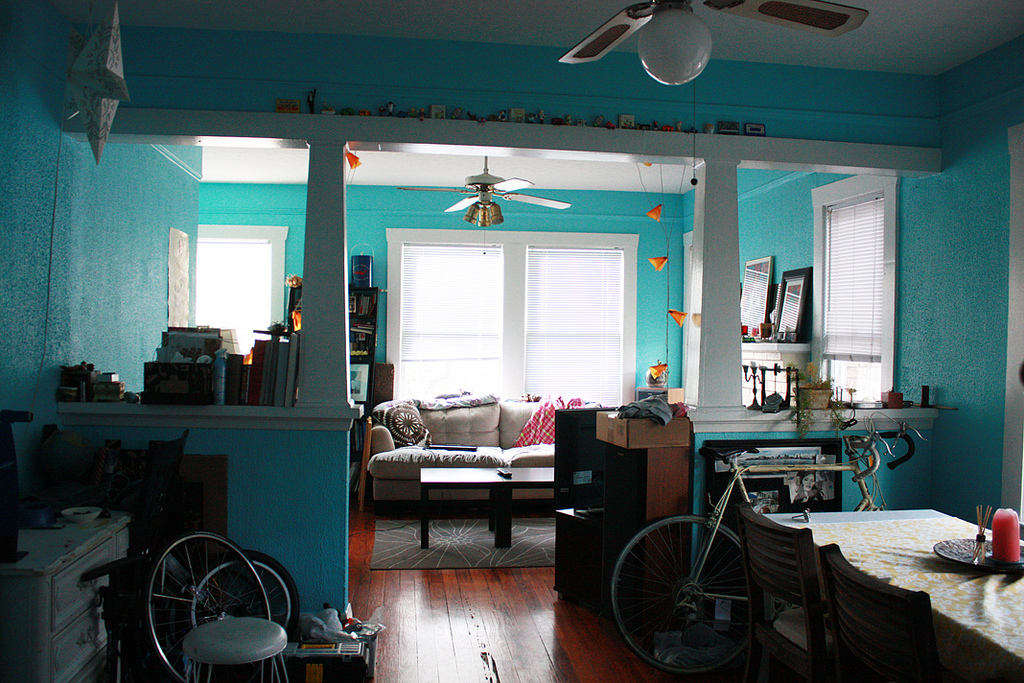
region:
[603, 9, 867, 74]
Ceiling fan hanging down from ceiling.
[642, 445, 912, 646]
Bike leaning against wall.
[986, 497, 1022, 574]
Red candle on plate on table.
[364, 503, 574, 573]
Gray and white area rug in room.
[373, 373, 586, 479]
Light colored in couch in room.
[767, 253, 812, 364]
Black framed picture leaning against wall.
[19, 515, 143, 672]
White distressed dresser in room.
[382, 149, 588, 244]
a ceiling fan with lights in the middle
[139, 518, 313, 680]
a set of spare bicycle tires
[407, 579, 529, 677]
dark stained wooden floors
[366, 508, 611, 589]
a piece of rug or carpet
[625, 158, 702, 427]
a decorative light stand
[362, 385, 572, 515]
a white couch with pillows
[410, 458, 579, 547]
a small wooden table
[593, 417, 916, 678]
a bicycle leaning on a wall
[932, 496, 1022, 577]
a candle and incense on a tray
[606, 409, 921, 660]
bicycle next to the wall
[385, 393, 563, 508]
couch under the windows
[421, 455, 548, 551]
coffee table in the living room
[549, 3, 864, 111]
ceiling fan with globe light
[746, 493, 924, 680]
chairs at the table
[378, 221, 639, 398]
windows behind the couch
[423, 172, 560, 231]
ceiling fan in the living room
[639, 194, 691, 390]
orange light fixtures next to the couch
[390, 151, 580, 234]
A CEILING FAN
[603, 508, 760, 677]
A REAR BIKE TIRE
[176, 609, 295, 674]
A ROUND WHITE STOOL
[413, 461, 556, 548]
A BROWN WOODEN COFFEE TABLE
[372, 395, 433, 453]
A COUCH THROW PILLOW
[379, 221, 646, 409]
TWO LIVING ROOM WINDOWS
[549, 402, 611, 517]
A FLAT SCREEN TV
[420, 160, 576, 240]
fan in the living room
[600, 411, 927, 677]
bike in the dining room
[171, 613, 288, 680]
stool with a grey seat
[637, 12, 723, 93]
round white light globe in the dining room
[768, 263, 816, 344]
black framed picture on the mantle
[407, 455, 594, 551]
wooden coffee table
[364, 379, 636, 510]
off white colored sofa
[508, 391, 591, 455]
red pillow on the couch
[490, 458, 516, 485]
remote on the coffee table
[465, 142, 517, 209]
a ceiling fan hanging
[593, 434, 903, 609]
a bike inside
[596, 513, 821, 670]
a bike tire inside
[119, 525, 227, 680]
a bike tire inside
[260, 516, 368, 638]
a bike tire inside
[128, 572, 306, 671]
a chair is inside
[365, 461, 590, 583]
a table on the rug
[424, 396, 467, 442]
a pillowo n the couch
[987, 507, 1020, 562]
wide red candle on a tray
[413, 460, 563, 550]
brown wooden coffee table on a rug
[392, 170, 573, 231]
silver and gold ceiling fan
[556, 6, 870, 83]
brown and silver ceiling fan with white globe light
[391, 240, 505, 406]
white shades hanging on a window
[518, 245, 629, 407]
white shades hanging on a window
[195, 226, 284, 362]
white shades hanging on a window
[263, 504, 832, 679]
dark brown wooden floor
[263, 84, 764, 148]
row of knick knacks sitting on high shelf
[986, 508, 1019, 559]
Candle on a plate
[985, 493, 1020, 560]
Candle on the table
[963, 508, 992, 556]
Reed diffuser on a plate